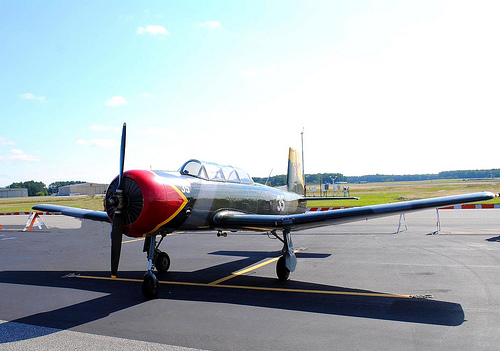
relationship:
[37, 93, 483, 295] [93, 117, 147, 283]
airplane has propeller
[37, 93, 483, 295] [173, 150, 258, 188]
airplane has hatch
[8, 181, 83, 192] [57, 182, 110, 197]
tree behind building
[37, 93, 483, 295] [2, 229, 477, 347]
airplane has shadow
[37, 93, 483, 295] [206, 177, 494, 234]
airplane has wing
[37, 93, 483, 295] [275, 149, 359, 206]
airplane has tail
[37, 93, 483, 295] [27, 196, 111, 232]
airplane has wing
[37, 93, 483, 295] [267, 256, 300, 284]
airplane has wheel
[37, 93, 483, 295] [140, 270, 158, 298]
airplane has wheel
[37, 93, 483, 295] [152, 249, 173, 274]
airplane has wheel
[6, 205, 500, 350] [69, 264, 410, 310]
asphalt has line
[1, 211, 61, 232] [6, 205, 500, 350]
barrier on asphalt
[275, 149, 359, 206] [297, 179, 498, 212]
tail near field